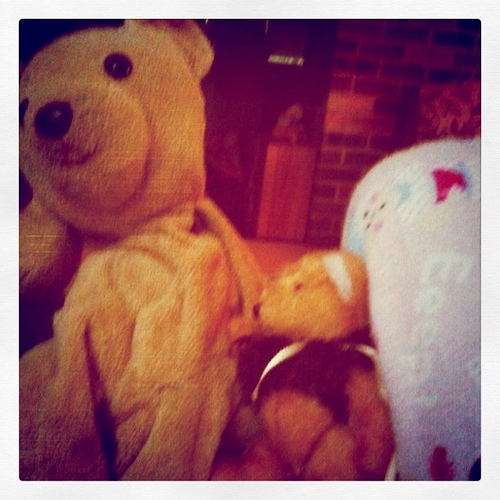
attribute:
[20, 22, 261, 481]
teddy bear — smiling, brown, floppy, big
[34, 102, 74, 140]
nose — black, big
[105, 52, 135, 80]
eye — large, round, black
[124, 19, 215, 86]
ear — rounded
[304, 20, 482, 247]
wall — small, brick, red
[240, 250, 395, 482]
cub — small, jointed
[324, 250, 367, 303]
ear — white, brown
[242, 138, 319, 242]
speaker — wooden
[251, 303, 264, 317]
nose — black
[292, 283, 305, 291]
eye — black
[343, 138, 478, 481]
cloth — pink, blue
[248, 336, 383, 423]
shirt — dark